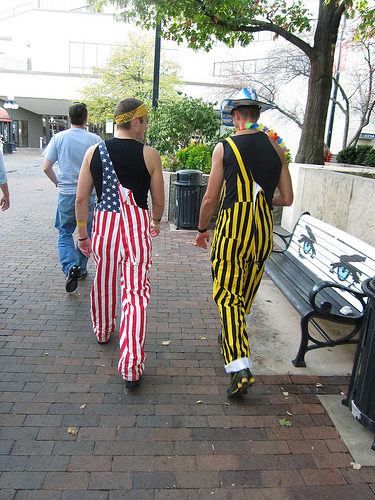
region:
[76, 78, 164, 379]
man wearing american flag overalls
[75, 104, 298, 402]
two wearing black shirts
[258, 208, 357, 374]
wooden bench on walkway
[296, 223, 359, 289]
eyes painted on wooden bench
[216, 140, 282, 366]
yellow and black striped overalls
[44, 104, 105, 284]
man wearing blue jeans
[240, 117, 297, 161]
multi colored lei of man in overalls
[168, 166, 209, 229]
black trashcan in front of men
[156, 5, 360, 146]
tree beside sidewalk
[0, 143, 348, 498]
brick pathway people are walking on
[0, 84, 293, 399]
four men walking on the sidewalk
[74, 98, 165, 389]
a man wearing blue, white and red overalls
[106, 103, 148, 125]
a yellow scarf tie around the man's forehead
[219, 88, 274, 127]
a blue and white cowboy hat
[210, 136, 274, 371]
yellow and black overalls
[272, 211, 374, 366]
a black and white bench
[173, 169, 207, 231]
a black trashcan in the rest area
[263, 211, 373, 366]
a black and white bench in a rest area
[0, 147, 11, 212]
the right arm of a man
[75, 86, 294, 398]
two young men walking in a rest area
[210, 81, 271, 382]
man with hat on.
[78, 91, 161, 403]
Man with no hat on.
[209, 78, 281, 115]
Hat on a man's head.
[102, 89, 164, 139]
No hat on a man's head.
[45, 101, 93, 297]
Man with blue shirt on.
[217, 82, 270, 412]
Man with yellow and black clothes on.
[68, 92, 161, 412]
Man with red, white, blue, black and yellow clothes on.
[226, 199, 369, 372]
Black bench sitting on pavement.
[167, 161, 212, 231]
Black trash can sitting on pavement.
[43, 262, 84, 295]
Black shoe on a man's foot.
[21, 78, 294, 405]
people walking down the sidewalk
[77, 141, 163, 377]
he is wearing American flag overalls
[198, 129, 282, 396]
black and yellow striped overalls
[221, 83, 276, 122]
he is wearing a blue cowboy hat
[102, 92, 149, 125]
he is wearing a yellow bandana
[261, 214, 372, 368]
a bench on the sidewalk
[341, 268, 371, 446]
a trash can by the bench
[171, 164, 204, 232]
a trash can by the planter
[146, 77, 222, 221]
trees in a planter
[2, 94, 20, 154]
a lightpole across the street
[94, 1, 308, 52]
green leaves on tree branch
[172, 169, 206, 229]
round black garbage can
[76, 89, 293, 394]
backs of two men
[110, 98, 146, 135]
yellow bandana on head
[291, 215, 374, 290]
bench with painted eyes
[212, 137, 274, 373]
black and yellow overalls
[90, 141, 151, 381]
clothing with flag print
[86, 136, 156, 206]
black tank top on body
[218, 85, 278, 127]
cowboy hat on head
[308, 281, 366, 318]
curved metal arm rest